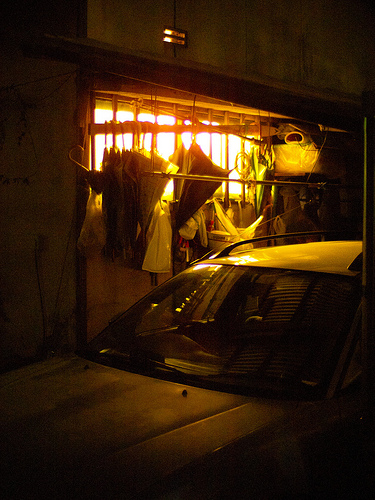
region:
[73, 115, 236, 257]
Umbrellas are hanging.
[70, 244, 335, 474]
One car is parked.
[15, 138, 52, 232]
Wall is white color.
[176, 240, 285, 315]
Light reflection is seen in car.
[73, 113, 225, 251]
Ten umbrellas are seen.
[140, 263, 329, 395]
reflection is seen in mirror.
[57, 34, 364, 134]
Rod is brown color.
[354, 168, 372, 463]
Pole is brown color.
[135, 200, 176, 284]
Cover is white color.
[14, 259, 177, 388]
Car is parked near the wall.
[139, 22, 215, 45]
small white line overhead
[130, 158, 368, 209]
long silver rail across stand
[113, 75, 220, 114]
edge of the stand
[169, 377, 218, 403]
small hole on front of car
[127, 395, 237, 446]
deep line in the car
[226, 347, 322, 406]
windshield on the car's front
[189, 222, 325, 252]
thick pole on top of car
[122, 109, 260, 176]
bright line in the small stand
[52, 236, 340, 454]
old fashioned car in front of stand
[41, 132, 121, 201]
brown handle of umbrella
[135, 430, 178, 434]
front part of a car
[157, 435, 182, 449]
bonnet of a car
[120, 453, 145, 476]
section of a cars body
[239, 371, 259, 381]
wipers of a car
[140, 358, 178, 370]
section of a wiper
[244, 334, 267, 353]
window of a car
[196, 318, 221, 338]
wind screen of a car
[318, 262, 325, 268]
upper part of a car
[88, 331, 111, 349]
edge of a car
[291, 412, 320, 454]
side of a car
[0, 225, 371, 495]
automobile in a garage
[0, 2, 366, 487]
white car in a dark garage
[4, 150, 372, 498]
vehicle parked inside a garage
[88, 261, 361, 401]
front windshield on the car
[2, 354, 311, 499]
hood on the automobile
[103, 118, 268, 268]
umbrellas hanging on a wooden pole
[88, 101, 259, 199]
window in the garage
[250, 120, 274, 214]
green umbrella hanging in garage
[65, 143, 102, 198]
handle on an umbrella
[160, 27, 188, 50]
vent in the garage's wall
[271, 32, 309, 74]
part of a wall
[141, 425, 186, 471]
part of a bonnet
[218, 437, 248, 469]
edge of a bonnet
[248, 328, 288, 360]
part of a window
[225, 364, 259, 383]
edge of a window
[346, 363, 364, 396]
part of a side mirror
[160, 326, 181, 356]
part of a window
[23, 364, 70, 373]
edge of a bnnet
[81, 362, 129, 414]
top of a bonnet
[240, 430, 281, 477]
edge of the car